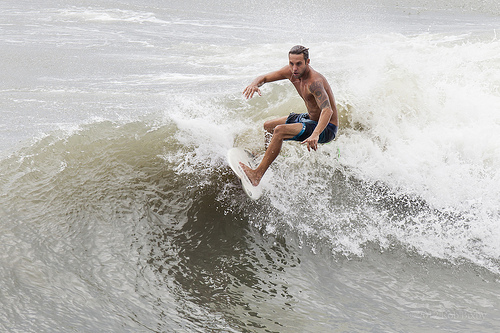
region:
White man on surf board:
[207, 42, 342, 206]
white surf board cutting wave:
[217, 145, 277, 203]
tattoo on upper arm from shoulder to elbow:
[302, 72, 333, 120]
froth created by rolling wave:
[370, 75, 487, 206]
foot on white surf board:
[232, 160, 271, 192]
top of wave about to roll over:
[31, 119, 133, 177]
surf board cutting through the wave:
[217, 145, 287, 210]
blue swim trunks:
[282, 106, 337, 147]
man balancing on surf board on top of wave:
[203, 28, 345, 207]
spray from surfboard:
[157, 114, 246, 164]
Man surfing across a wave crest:
[9, 7, 498, 324]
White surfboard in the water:
[223, 142, 263, 197]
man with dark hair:
[245, 42, 350, 194]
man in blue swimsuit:
[247, 43, 349, 199]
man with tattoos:
[242, 42, 346, 200]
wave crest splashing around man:
[349, 28, 496, 268]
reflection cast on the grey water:
[160, 180, 289, 330]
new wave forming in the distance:
[52, 0, 251, 46]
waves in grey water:
[13, 75, 498, 332]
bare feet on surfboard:
[227, 135, 286, 203]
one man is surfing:
[214, 46, 341, 233]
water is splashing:
[396, 55, 486, 187]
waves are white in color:
[174, 115, 226, 152]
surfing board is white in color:
[226, 148, 259, 183]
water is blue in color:
[24, 26, 96, 62]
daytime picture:
[54, 53, 468, 310]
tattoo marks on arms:
[311, 76, 330, 109]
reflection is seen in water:
[181, 172, 291, 332]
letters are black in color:
[238, 158, 250, 189]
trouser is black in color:
[271, 102, 341, 152]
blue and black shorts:
[276, 103, 348, 153]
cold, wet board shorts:
[279, 103, 367, 159]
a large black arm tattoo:
[303, 77, 338, 112]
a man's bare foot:
[238, 157, 275, 187]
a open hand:
[241, 74, 268, 109]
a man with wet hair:
[281, 31, 320, 86]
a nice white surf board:
[216, 124, 296, 204]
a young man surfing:
[207, 15, 350, 208]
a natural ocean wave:
[63, 6, 488, 303]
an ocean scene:
[35, 6, 494, 321]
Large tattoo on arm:
[308, 80, 333, 112]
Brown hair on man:
[290, 43, 310, 59]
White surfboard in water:
[229, 146, 271, 203]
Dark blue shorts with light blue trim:
[290, 111, 338, 143]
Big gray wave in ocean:
[7, 51, 489, 283]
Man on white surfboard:
[240, 39, 340, 184]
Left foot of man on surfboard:
[241, 160, 266, 190]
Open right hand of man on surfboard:
[241, 82, 262, 99]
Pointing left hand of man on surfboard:
[300, 136, 318, 151]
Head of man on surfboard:
[287, 45, 311, 77]